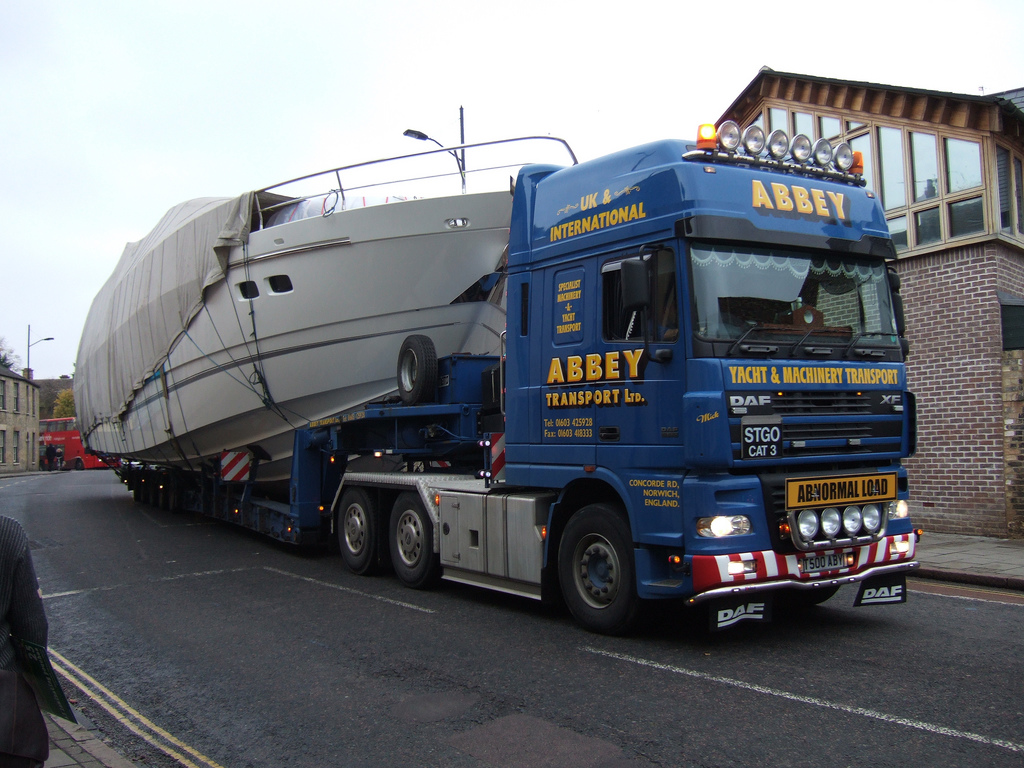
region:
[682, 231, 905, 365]
A windshield on a truck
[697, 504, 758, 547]
A headlight on a truck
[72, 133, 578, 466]
A white boat on a trailer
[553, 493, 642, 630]
Tires on a truck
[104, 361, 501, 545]
A blue trailer hauling a boat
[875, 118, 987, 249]
Windows on a building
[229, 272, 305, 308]
Windows on a boat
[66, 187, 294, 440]
A tarp on a boat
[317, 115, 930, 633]
yellow and blue truck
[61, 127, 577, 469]
large white motor boat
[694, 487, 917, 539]
two bright headlights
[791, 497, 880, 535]
four front head lights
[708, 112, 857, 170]
six lights on top of truck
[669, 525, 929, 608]
red and white front bumper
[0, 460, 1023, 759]
driveway with white lines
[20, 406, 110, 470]
red truck in back ground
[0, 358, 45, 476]
brick building on left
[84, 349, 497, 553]
a long blue trailor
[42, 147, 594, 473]
THE BOAT IS WHITE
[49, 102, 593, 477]
THE BOAT IS BIG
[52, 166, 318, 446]
THE TARP IS WHITE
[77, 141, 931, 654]
THE TRUCK IS BLUE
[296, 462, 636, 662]
THE WHEELS ON THE TRUCK ARE BLACK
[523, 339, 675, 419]
THE WRITING ON THE TRUCK IS YELLOW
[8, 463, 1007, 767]
THE ROAD IS DIRTY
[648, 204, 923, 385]
THE TRUCK HAS A BIG WINDSHIELD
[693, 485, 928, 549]
THE TRUCK HAS MANY LIGHTS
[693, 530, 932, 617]
THE BUMPER IS RED AND WHITE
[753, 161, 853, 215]
word on the truck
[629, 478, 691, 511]
word on the truck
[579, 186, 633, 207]
word on the truck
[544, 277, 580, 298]
word on the truck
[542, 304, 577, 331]
word on the truck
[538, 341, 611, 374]
word on the truck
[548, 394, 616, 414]
word on the truck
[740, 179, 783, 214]
letter on the bus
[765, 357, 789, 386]
letter on the bus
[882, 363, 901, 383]
letter on the bus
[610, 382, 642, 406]
letter on the bus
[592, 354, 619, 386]
letter on the bus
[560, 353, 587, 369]
letter on the bus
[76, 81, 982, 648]
truck carrying a boat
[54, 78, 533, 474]
the boat is whie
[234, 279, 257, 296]
a window on a boat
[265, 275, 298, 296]
a window on a boat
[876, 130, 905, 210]
a window on a building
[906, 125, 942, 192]
a window on a building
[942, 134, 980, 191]
a window on a building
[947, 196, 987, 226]
a window on a building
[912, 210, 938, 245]
a window on a building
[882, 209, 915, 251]
a window on a building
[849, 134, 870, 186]
a window on a building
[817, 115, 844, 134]
a window on a building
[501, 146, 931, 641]
large blue truck for moving wide loads and heavy equipment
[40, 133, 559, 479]
large cruiser boat being transported over the road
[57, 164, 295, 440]
canvas covering the cabin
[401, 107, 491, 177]
top of a street light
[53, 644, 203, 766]
double solid line paintedont he side of the road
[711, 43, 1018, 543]
brick building with windows covering the second floor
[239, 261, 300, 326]
windows for the lower level of the boat